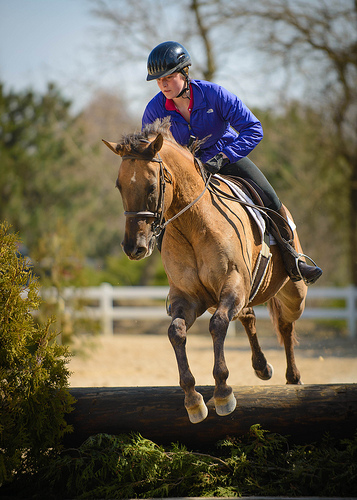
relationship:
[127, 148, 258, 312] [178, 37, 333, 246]
horse with rider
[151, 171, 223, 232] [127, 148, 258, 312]
bridle on horse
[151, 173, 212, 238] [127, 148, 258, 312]
bridle on horse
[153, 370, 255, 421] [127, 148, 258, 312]
hooves on horse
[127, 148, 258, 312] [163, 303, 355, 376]
horse has legs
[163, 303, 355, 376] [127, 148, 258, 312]
legs of horse